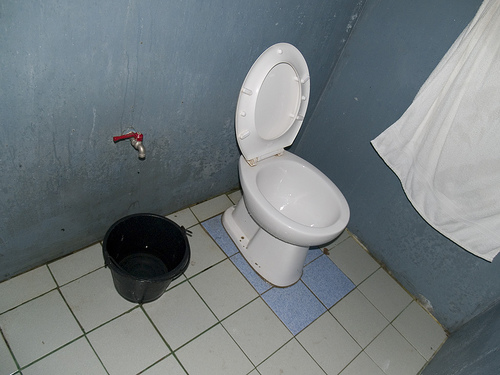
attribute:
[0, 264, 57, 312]
tile — white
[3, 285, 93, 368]
tile — white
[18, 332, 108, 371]
tile — white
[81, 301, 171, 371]
tile — white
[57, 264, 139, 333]
tile — white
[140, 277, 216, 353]
tile — white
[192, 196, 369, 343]
tiles — blue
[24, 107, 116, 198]
stains — water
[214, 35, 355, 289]
bowl — clean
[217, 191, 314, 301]
base — dirty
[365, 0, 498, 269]
towel — white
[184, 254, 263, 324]
tile — white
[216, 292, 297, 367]
tile — white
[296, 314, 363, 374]
tile — white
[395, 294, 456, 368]
tile — white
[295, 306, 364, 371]
tile — white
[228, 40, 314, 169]
lid — open, plastic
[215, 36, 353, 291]
toilet — white, ceramic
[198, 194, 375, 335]
tiles — blue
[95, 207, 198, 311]
bucket — black, small, round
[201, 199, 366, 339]
tiles — blue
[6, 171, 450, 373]
tiles — white, square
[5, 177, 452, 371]
tile — white, ceramic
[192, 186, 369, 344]
tile — blue, accent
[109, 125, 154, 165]
spigot — water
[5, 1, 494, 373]
bathroom — dirty